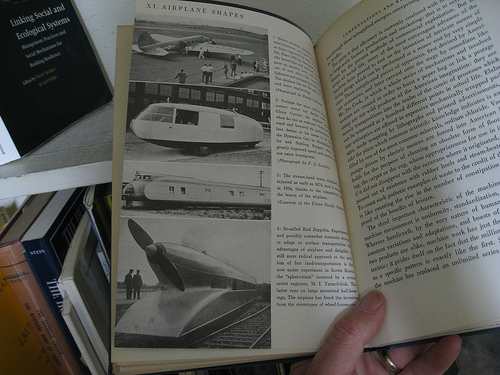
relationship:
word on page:
[312, 202, 323, 207] [111, 0, 371, 362]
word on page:
[281, 98, 295, 106] [111, 0, 371, 362]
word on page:
[302, 95, 312, 102] [111, 0, 371, 362]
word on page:
[375, 11, 392, 24] [314, 0, 500, 346]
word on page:
[403, 51, 425, 67] [314, 0, 500, 346]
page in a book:
[111, 0, 371, 362] [107, 1, 500, 375]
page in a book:
[314, 0, 500, 346] [107, 1, 500, 375]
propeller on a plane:
[128, 219, 186, 292] [116, 218, 260, 348]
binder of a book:
[20, 240, 83, 374] [20, 185, 87, 373]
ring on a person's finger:
[379, 348, 400, 374] [374, 341, 435, 372]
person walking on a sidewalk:
[231, 59, 237, 76] [203, 69, 268, 85]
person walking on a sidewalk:
[207, 63, 214, 82] [203, 69, 268, 85]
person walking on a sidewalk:
[175, 69, 188, 85] [203, 69, 268, 85]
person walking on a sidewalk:
[223, 60, 228, 78] [203, 69, 268, 85]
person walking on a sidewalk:
[255, 58, 260, 72] [203, 69, 268, 85]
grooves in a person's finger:
[336, 322, 355, 338] [301, 290, 385, 375]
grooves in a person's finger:
[342, 315, 362, 334] [301, 290, 385, 375]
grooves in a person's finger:
[333, 324, 346, 340] [301, 290, 385, 375]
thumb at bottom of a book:
[301, 290, 385, 375] [107, 1, 500, 375]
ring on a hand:
[379, 348, 400, 374] [291, 291, 463, 374]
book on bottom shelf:
[20, 185, 87, 373] [0, 182, 112, 374]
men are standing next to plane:
[126, 268, 143, 301] [116, 218, 260, 348]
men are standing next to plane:
[126, 268, 133, 301] [116, 218, 260, 348]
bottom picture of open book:
[113, 217, 272, 350] [107, 1, 500, 375]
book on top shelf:
[0, 3, 114, 165] [0, 84, 114, 201]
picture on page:
[127, 11, 270, 89] [111, 0, 371, 362]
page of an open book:
[111, 0, 371, 362] [107, 1, 500, 375]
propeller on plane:
[128, 219, 186, 292] [116, 218, 260, 348]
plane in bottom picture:
[116, 218, 260, 348] [113, 217, 272, 350]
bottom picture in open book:
[113, 217, 272, 350] [107, 1, 500, 375]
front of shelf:
[0, 161, 114, 199] [0, 84, 114, 201]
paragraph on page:
[363, 181, 499, 289] [314, 0, 500, 346]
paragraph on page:
[275, 226, 359, 307] [111, 0, 371, 362]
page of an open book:
[314, 0, 500, 346] [107, 1, 500, 375]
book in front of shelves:
[107, 1, 500, 375] [1, 0, 499, 374]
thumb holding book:
[301, 290, 385, 375] [107, 1, 500, 375]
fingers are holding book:
[361, 336, 463, 375] [107, 1, 500, 375]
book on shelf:
[0, 3, 114, 165] [0, 84, 114, 201]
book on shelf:
[2, 191, 86, 370] [0, 182, 112, 374]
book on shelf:
[20, 185, 87, 373] [0, 182, 112, 374]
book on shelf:
[60, 293, 107, 374] [0, 182, 112, 374]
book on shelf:
[82, 185, 109, 265] [0, 182, 112, 374]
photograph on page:
[127, 11, 270, 89] [111, 0, 371, 362]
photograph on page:
[123, 81, 270, 167] [111, 0, 371, 362]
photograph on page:
[113, 217, 272, 350] [111, 0, 371, 362]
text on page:
[275, 38, 359, 307] [111, 0, 371, 362]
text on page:
[147, 3, 244, 20] [111, 0, 371, 362]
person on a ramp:
[175, 69, 188, 85] [190, 63, 268, 87]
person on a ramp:
[207, 63, 214, 82] [190, 63, 268, 87]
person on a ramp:
[223, 60, 228, 78] [190, 63, 268, 87]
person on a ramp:
[231, 59, 237, 76] [190, 63, 268, 87]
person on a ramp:
[255, 58, 260, 72] [190, 63, 268, 87]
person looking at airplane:
[175, 69, 188, 85] [132, 31, 253, 60]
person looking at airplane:
[207, 63, 214, 82] [132, 31, 253, 60]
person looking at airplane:
[223, 60, 228, 78] [132, 31, 253, 60]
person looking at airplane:
[231, 59, 237, 76] [132, 31, 253, 60]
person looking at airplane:
[255, 58, 260, 72] [132, 31, 253, 60]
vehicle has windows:
[130, 102, 264, 155] [175, 109, 200, 124]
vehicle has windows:
[130, 102, 264, 155] [221, 112, 235, 127]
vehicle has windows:
[130, 102, 264, 155] [138, 104, 174, 122]